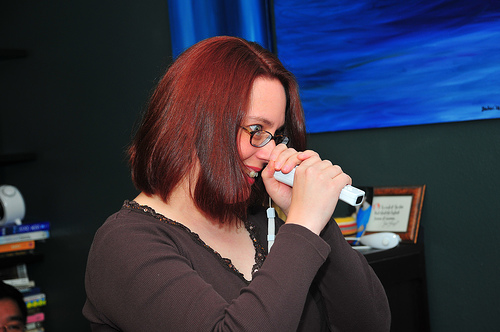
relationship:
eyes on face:
[245, 122, 266, 138] [212, 73, 292, 212]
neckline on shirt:
[118, 188, 271, 284] [85, 175, 391, 330]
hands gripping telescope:
[257, 139, 317, 229] [264, 156, 366, 212]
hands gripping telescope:
[285, 148, 354, 229] [264, 156, 366, 212]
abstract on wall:
[165, 3, 497, 161] [4, 5, 495, 330]